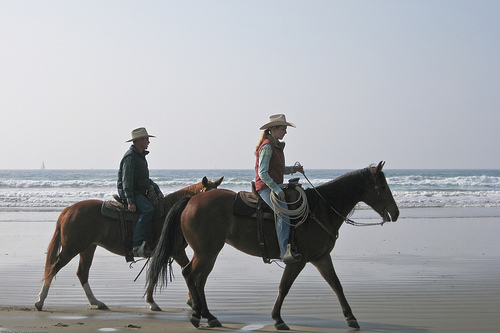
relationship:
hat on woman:
[254, 110, 304, 131] [244, 99, 315, 256]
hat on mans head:
[125, 127, 155, 141] [132, 126, 149, 151]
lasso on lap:
[270, 184, 310, 227] [251, 168, 318, 223]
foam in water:
[0, 174, 498, 212] [2, 168, 499, 210]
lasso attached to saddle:
[270, 180, 310, 225] [233, 176, 310, 263]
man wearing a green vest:
[116, 127, 164, 256] [112, 145, 157, 199]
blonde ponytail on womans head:
[252, 117, 275, 153] [258, 118, 307, 143]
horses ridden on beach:
[144, 160, 401, 331] [405, 152, 499, 314]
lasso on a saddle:
[270, 184, 310, 227] [233, 190, 264, 220]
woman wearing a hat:
[254, 114, 304, 259] [256, 113, 295, 131]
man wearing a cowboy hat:
[116, 127, 161, 256] [125, 127, 155, 141]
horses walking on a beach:
[133, 158, 401, 331] [3, 212, 499, 332]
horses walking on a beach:
[29, 177, 224, 309] [3, 212, 499, 332]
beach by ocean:
[3, 212, 499, 332] [1, 167, 498, 213]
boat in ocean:
[38, 158, 58, 180] [0, 170, 497, 222]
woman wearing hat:
[254, 114, 304, 259] [260, 113, 296, 130]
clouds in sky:
[0, 0, 499, 169] [328, 23, 439, 128]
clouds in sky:
[0, 0, 499, 169] [0, 0, 499, 170]